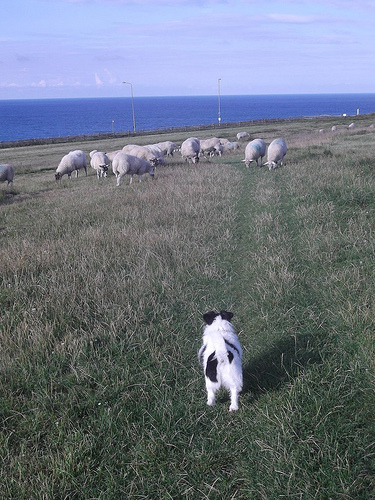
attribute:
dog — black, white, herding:
[176, 296, 272, 423]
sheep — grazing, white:
[53, 116, 289, 189]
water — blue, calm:
[5, 92, 119, 142]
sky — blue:
[0, 4, 185, 71]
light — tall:
[213, 70, 231, 133]